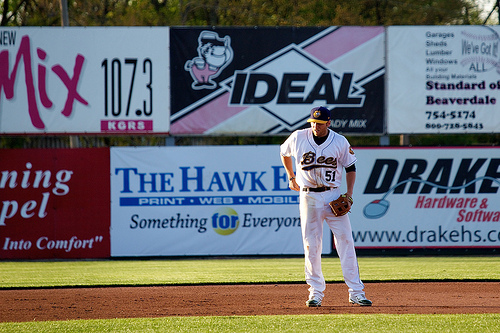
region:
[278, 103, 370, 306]
Baseball player with Bees jersey on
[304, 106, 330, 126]
dark colored cap with yellow on it.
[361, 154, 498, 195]
The word DRAKE on a banner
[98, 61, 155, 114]
Black numbers 107.3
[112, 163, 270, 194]
THE HAWK in blue letters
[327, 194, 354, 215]
Light colored baseball glove on a hand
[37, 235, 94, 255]
The word Comfort in white lettering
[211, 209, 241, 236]
yellow circle with blue lettered word for inside.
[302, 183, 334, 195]
Dark belt around mans waist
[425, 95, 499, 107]
The word Beaverdale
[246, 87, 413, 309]
A baseball player looks on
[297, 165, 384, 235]
Baseball player's mitt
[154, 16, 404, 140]
Advertisement for "IDEAL"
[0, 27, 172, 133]
Advertisment for a radio station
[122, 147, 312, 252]
Advertisement for "The Hawk Eye"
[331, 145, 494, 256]
Advertisement for Drake Hardware and Software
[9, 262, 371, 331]
The grass and dirt of a baseball field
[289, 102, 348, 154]
Baseball player wearing his cap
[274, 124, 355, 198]
A baseball jersey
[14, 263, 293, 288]
Lawn on a baseball field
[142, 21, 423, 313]
Picture of a baseball player.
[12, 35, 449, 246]
Different advertising on wall in background.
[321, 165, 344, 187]
The number 51 in dark color.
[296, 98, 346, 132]
A team baseball hat.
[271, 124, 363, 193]
A baseball team jersey.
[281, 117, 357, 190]
A short sleeve shirt.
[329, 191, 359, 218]
Baseball glove on left hand.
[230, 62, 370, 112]
The word IDEAL in large dark letters.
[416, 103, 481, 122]
The telepone number 754-5174.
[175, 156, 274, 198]
The word HAWK in blue letters.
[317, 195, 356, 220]
Brown and yellow base ball glove.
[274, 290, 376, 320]
White and black tennis shoes.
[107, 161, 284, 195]
Blue letters that say the hawk.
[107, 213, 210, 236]
Black letters that say something.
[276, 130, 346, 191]
Baseball jersey with the number 51 on it.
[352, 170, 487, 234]
Drawing of a computer mouse.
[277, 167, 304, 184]
Watch on a persons arm.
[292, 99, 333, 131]
Black and yellow base ball hat.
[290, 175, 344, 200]
Dark belt around white pants.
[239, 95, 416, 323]
Baseball player on field.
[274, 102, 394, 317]
the pitcher is standing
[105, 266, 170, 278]
the turf is green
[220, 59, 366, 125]
the sign says ideal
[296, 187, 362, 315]
the pants are white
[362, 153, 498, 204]
the sign says drake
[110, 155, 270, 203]
the sign says the hawk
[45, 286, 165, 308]
the dirt is red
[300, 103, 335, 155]
the man is wearing a hat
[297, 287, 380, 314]
the man has shoes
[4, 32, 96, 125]
the sign says the mix